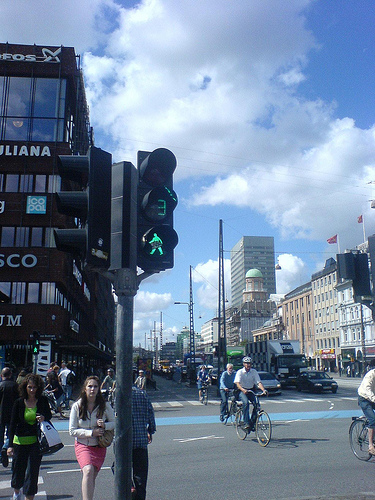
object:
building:
[0, 40, 116, 390]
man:
[234, 356, 269, 432]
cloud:
[83, 51, 115, 97]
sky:
[0, 2, 371, 351]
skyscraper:
[230, 235, 276, 313]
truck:
[226, 347, 244, 372]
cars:
[208, 368, 222, 385]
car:
[254, 371, 282, 395]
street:
[0, 357, 373, 500]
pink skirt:
[74, 439, 107, 471]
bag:
[34, 421, 62, 456]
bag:
[98, 424, 115, 448]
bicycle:
[235, 390, 272, 445]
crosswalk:
[0, 424, 37, 499]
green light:
[147, 232, 167, 257]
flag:
[327, 234, 338, 245]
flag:
[357, 215, 363, 223]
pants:
[235, 390, 257, 426]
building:
[229, 268, 278, 343]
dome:
[246, 268, 263, 278]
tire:
[348, 419, 373, 461]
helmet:
[242, 356, 252, 363]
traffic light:
[52, 229, 86, 253]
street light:
[140, 184, 179, 225]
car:
[296, 370, 338, 393]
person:
[219, 363, 236, 422]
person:
[197, 365, 211, 401]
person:
[134, 370, 146, 393]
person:
[357, 369, 375, 457]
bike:
[348, 415, 374, 462]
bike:
[219, 388, 242, 426]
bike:
[197, 378, 212, 405]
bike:
[102, 389, 115, 409]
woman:
[67, 373, 117, 498]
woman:
[0, 372, 52, 498]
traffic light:
[138, 146, 177, 184]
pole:
[107, 160, 138, 497]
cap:
[242, 356, 253, 364]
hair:
[226, 362, 234, 369]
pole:
[336, 233, 340, 254]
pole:
[362, 212, 366, 243]